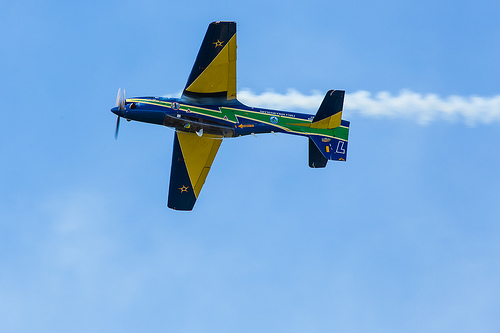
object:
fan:
[110, 87, 126, 140]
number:
[260, 109, 296, 117]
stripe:
[126, 85, 500, 141]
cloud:
[0, 0, 499, 333]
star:
[178, 185, 190, 193]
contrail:
[162, 87, 499, 129]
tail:
[308, 89, 351, 168]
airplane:
[110, 20, 351, 210]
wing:
[310, 89, 345, 128]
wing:
[308, 137, 328, 169]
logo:
[271, 117, 279, 124]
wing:
[181, 22, 237, 100]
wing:
[167, 128, 223, 211]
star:
[213, 39, 224, 48]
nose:
[110, 87, 135, 141]